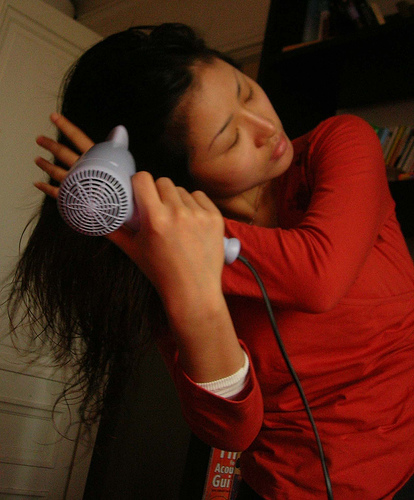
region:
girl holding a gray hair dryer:
[58, 119, 241, 269]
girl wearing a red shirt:
[171, 113, 412, 495]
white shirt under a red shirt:
[186, 352, 254, 398]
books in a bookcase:
[255, 2, 412, 245]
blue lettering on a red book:
[212, 448, 233, 491]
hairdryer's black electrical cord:
[235, 252, 342, 498]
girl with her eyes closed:
[219, 78, 258, 160]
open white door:
[2, 0, 96, 498]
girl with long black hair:
[0, 19, 219, 463]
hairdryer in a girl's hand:
[59, 123, 244, 274]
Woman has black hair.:
[110, 48, 172, 130]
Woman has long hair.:
[57, 336, 131, 398]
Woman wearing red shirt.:
[317, 349, 373, 421]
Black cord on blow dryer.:
[243, 259, 332, 464]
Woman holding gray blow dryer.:
[83, 157, 223, 283]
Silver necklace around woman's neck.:
[242, 204, 271, 233]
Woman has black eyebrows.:
[222, 46, 250, 177]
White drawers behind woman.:
[8, 386, 100, 495]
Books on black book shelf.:
[375, 117, 412, 194]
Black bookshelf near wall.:
[255, 43, 346, 103]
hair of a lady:
[119, 17, 176, 105]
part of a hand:
[204, 339, 249, 400]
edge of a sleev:
[218, 370, 254, 426]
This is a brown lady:
[21, 11, 411, 498]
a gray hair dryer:
[54, 123, 242, 261]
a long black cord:
[235, 255, 341, 498]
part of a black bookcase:
[82, 351, 187, 498]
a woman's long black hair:
[0, 21, 244, 458]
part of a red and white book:
[200, 443, 240, 498]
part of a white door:
[2, 0, 104, 499]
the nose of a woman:
[233, 107, 280, 148]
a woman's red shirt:
[168, 116, 412, 498]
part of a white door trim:
[206, 32, 262, 64]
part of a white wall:
[182, 2, 268, 26]